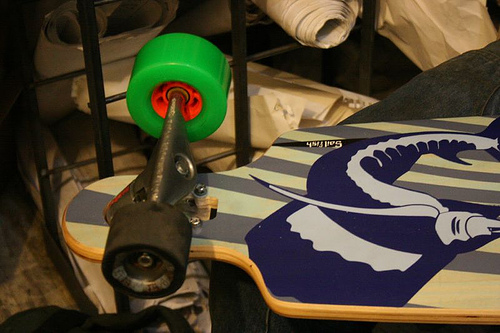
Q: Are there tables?
A: No, there are no tables.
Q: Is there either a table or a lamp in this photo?
A: No, there are no tables or lamps.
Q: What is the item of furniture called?
A: The piece of furniture is a shelf.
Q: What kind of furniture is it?
A: The piece of furniture is a shelf.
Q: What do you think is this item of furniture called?
A: This is a shelf.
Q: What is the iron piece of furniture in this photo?
A: The piece of furniture is a shelf.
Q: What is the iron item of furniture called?
A: The piece of furniture is a shelf.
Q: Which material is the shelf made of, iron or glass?
A: The shelf is made of iron.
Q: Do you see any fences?
A: No, there are no fences.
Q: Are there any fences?
A: No, there are no fences.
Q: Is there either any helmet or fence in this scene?
A: No, there are no fences or helmets.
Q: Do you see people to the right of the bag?
A: Yes, there is a person to the right of the bag.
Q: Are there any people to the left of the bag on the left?
A: No, the person is to the right of the bag.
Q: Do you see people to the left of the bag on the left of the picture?
A: No, the person is to the right of the bag.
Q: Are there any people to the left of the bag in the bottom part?
A: No, the person is to the right of the bag.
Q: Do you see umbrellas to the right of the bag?
A: No, there is a person to the right of the bag.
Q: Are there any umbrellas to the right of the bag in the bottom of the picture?
A: No, there is a person to the right of the bag.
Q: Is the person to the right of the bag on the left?
A: Yes, the person is to the right of the bag.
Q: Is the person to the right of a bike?
A: No, the person is to the right of the bag.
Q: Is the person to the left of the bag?
A: No, the person is to the right of the bag.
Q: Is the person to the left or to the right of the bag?
A: The person is to the right of the bag.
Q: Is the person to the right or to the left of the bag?
A: The person is to the right of the bag.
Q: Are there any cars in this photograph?
A: No, there are no cars.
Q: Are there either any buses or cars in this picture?
A: No, there are no cars or buses.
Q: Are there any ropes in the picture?
A: No, there are no ropes.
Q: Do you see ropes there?
A: No, there are no ropes.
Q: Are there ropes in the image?
A: No, there are no ropes.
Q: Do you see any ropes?
A: No, there are no ropes.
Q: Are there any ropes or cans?
A: No, there are no ropes or cans.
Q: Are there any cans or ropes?
A: No, there are no ropes or cans.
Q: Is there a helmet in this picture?
A: No, there are no helmets.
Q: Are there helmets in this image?
A: No, there are no helmets.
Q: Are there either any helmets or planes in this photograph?
A: No, there are no helmets or planes.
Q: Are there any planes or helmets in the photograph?
A: No, there are no helmets or planes.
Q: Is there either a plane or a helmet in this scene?
A: No, there are no helmets or airplanes.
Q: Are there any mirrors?
A: No, there are no mirrors.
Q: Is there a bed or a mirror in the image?
A: No, there are no mirrors or beds.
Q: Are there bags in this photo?
A: Yes, there is a bag.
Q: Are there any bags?
A: Yes, there is a bag.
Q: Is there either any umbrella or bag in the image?
A: Yes, there is a bag.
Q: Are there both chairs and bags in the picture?
A: No, there is a bag but no chairs.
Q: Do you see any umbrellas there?
A: No, there are no umbrellas.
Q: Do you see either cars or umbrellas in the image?
A: No, there are no umbrellas or cars.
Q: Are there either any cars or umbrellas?
A: No, there are no umbrellas or cars.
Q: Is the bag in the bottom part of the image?
A: Yes, the bag is in the bottom of the image.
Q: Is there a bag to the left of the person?
A: Yes, there is a bag to the left of the person.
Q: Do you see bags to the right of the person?
A: No, the bag is to the left of the person.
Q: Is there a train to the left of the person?
A: No, there is a bag to the left of the person.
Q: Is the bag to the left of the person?
A: Yes, the bag is to the left of the person.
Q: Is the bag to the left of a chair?
A: No, the bag is to the left of the person.